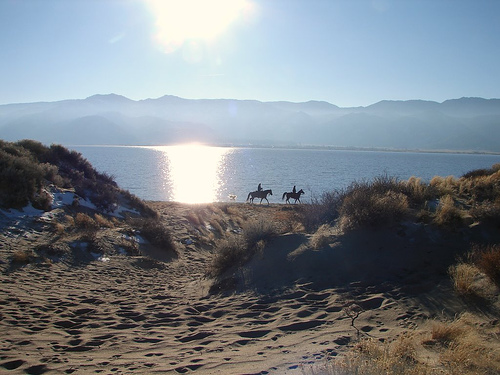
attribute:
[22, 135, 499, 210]
water — calm, smooth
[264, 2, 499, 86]
blue sky — blue 